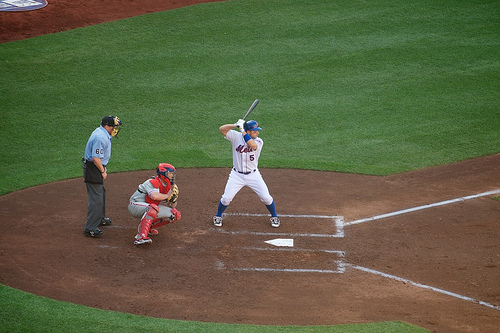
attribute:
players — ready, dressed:
[211, 119, 281, 228]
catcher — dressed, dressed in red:
[128, 163, 183, 246]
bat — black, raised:
[236, 99, 265, 126]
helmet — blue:
[243, 120, 262, 130]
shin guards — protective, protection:
[135, 203, 159, 239]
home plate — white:
[264, 237, 295, 250]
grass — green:
[2, 1, 498, 331]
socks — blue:
[265, 201, 278, 216]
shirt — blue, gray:
[81, 125, 112, 167]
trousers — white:
[219, 168, 274, 206]